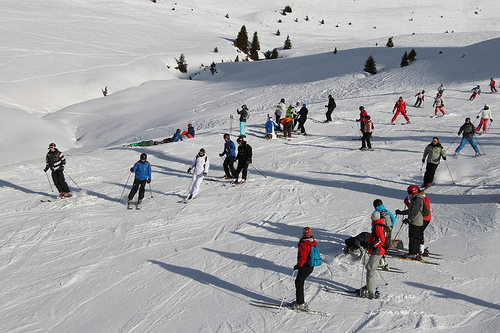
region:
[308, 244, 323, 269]
turquoise backpack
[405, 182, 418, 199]
red helmet for skiing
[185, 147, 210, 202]
person wearing all white snowgear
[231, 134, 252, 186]
skiier wearing all black snowgear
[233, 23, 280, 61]
small group of pine tree towards the bottom of the hill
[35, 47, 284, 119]
small valley at the bottom of the hill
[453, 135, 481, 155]
dark turquoise snowpants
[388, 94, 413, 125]
all red snowsuit with a black winter hat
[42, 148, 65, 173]
black winter coat with white stripes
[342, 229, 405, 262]
snowboarder crashed on the ground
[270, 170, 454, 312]
people on the side of a ski slope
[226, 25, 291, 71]
trees on the ski slope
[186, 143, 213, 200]
person wearing a white ski suit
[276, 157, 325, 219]
ski tracks in the snow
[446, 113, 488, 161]
person with legs spread far apart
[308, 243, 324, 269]
person with a blue back pack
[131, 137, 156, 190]
person wearing a blue ski jacket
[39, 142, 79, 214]
person skiing in the snow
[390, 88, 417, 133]
person wearing a red ski suit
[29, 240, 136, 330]
white snow covering the ground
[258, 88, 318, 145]
A group of children playing at the ski slope.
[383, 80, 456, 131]
Novice skiers learning how to ski.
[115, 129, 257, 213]
A group of skiers enjoying the slopes.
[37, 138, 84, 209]
Skier having fun at the slopes.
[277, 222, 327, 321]
A skier is watching the slopes from afar.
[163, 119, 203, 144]
A couple is enjoying their time at the slopes.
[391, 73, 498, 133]
A group of skiers are playing games in the snow.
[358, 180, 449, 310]
Skiers are deciding what route to take.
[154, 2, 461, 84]
Snowy tundra with sparse trees.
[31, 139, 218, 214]
Skiers having fun next to a small ravine.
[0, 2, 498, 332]
the snow on the ground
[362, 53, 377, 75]
the green tree in the snow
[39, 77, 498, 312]
the people on the snow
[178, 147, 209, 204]
the skier on the snow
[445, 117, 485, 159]
the skier with their legs far apart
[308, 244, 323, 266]
the backpack on the skier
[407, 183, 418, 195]
the helmet on the skier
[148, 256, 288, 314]
the shadow of the skier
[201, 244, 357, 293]
the shadow of the skier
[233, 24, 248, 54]
the green tree in the snow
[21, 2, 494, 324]
people skiing on the mountain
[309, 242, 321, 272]
blue backpack on a woman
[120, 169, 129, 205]
ski pole in man's hand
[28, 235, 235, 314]
white snow on the ground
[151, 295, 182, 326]
ski tracks in the snow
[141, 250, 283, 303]
shadows in the snow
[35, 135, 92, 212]
skier in the snow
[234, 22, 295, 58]
trees in the snow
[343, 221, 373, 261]
person lying on the ground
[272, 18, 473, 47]
bottom of the hill